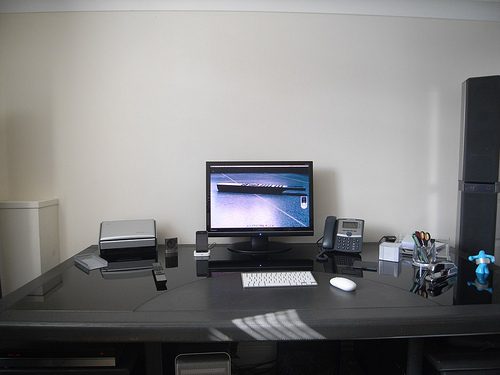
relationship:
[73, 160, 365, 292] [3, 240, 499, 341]
electronics on desk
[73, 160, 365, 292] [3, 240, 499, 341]
electronics are on desk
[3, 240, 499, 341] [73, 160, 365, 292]
desk has electronics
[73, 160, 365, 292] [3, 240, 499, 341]
electronics are stored on desk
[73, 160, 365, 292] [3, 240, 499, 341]
electronics are set on desk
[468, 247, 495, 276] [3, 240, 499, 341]
toy on desk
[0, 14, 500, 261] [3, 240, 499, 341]
wall by desk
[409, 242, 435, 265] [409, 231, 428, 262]
cup filled with pens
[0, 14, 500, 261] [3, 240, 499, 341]
wall behind desk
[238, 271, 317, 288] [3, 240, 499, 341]
keyboard on desk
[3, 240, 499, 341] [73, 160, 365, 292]
desk topped with electronics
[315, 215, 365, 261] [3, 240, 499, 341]
telephone on desk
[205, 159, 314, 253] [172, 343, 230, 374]
monitor for computer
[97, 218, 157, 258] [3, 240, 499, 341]
printer on desk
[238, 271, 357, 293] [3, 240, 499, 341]
keyboar and mouse are on desk